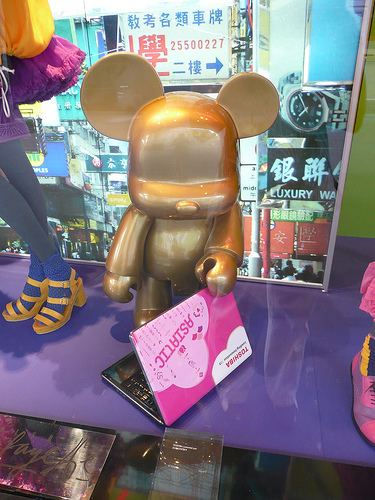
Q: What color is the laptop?
A: Pink.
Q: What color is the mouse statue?
A: Copper.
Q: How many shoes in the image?
A: Three.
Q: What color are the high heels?
A: Orange.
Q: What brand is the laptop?
A: Toshiba.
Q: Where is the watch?
A: On the backdrop.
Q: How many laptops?
A: One.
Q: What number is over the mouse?
A: 25500227.